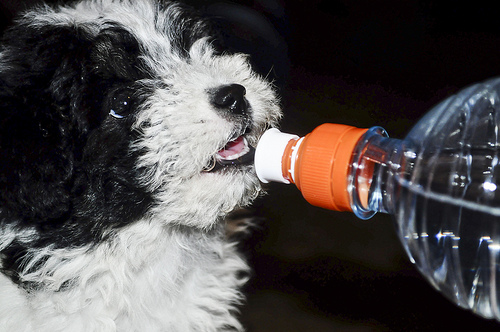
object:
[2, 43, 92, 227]
ear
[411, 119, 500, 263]
water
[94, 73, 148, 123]
eye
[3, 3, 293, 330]
dog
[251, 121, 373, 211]
top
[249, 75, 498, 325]
bottle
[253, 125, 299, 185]
nozzle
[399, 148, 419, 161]
light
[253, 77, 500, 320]
water bottle